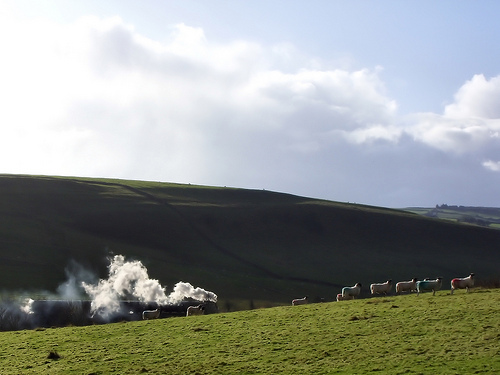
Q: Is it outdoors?
A: Yes, it is outdoors.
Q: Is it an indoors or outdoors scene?
A: It is outdoors.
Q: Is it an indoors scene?
A: No, it is outdoors.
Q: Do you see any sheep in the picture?
A: Yes, there is a sheep.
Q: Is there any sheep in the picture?
A: Yes, there is a sheep.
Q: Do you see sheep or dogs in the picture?
A: Yes, there is a sheep.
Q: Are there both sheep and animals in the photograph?
A: Yes, there are both a sheep and animals.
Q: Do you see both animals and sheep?
A: Yes, there are both a sheep and animals.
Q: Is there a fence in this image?
A: No, there are no fences.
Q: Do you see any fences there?
A: No, there are no fences.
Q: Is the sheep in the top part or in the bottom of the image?
A: The sheep is in the bottom of the image.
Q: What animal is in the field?
A: The animal is a sheep.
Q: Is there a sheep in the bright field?
A: Yes, there is a sheep in the field.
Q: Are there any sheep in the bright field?
A: Yes, there is a sheep in the field.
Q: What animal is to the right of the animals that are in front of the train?
A: The animal is a sheep.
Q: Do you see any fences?
A: No, there are no fences.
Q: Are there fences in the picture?
A: No, there are no fences.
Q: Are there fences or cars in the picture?
A: No, there are no fences or cars.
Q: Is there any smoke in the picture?
A: Yes, there is smoke.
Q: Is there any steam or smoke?
A: Yes, there is smoke.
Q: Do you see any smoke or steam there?
A: Yes, there is smoke.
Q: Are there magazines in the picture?
A: No, there are no magazines.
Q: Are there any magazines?
A: No, there are no magazines.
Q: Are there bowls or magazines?
A: No, there are no magazines or bowls.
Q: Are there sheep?
A: Yes, there is a sheep.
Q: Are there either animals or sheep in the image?
A: Yes, there is a sheep.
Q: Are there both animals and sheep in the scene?
A: Yes, there are both a sheep and animals.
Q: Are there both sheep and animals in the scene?
A: Yes, there are both a sheep and animals.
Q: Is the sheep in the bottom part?
A: Yes, the sheep is in the bottom of the image.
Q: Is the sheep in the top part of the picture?
A: No, the sheep is in the bottom of the image.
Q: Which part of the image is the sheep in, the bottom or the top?
A: The sheep is in the bottom of the image.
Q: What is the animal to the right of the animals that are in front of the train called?
A: The animal is a sheep.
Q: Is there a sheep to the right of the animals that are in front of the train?
A: Yes, there is a sheep to the right of the animals.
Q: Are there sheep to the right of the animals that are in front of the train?
A: Yes, there is a sheep to the right of the animals.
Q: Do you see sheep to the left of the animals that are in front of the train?
A: No, the sheep is to the right of the animals.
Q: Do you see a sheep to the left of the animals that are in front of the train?
A: No, the sheep is to the right of the animals.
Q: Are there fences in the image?
A: No, there are no fences.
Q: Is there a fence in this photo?
A: No, there are no fences.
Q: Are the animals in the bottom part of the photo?
A: Yes, the animals are in the bottom of the image.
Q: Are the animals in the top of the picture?
A: No, the animals are in the bottom of the image.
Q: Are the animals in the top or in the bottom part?
A: The animals are in the bottom of the image.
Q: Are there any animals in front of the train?
A: Yes, there are animals in front of the train.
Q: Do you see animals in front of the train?
A: Yes, there are animals in front of the train.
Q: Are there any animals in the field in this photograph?
A: Yes, there are animals in the field.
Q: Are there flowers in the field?
A: No, there are animals in the field.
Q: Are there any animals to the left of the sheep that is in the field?
A: Yes, there are animals to the left of the sheep.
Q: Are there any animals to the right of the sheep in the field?
A: No, the animals are to the left of the sheep.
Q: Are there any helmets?
A: No, there are no helmets.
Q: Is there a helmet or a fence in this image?
A: No, there are no helmets or fences.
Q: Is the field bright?
A: Yes, the field is bright.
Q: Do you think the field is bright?
A: Yes, the field is bright.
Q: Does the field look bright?
A: Yes, the field is bright.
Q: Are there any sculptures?
A: No, there are no sculptures.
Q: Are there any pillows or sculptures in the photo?
A: No, there are no sculptures or pillows.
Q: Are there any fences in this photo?
A: No, there are no fences.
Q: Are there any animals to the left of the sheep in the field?
A: Yes, there is an animal to the left of the sheep.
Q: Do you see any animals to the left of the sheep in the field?
A: Yes, there is an animal to the left of the sheep.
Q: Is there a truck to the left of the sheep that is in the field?
A: No, there is an animal to the left of the sheep.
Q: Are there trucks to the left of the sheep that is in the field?
A: No, there is an animal to the left of the sheep.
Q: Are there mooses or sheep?
A: Yes, there is a sheep.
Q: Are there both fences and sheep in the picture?
A: No, there is a sheep but no fences.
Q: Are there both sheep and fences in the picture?
A: No, there is a sheep but no fences.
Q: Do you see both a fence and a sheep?
A: No, there is a sheep but no fences.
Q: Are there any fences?
A: No, there are no fences.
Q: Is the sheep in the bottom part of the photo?
A: Yes, the sheep is in the bottom of the image.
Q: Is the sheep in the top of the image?
A: No, the sheep is in the bottom of the image.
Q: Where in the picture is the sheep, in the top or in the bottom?
A: The sheep is in the bottom of the image.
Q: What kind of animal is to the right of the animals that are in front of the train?
A: The animal is a sheep.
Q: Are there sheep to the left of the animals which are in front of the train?
A: No, the sheep is to the right of the animals.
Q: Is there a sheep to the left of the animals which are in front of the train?
A: No, the sheep is to the right of the animals.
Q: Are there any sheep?
A: Yes, there is a sheep.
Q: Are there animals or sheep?
A: Yes, there is a sheep.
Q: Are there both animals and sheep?
A: Yes, there are both a sheep and an animal.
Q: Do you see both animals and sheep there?
A: Yes, there are both a sheep and an animal.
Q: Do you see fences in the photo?
A: No, there are no fences.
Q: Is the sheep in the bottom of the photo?
A: Yes, the sheep is in the bottom of the image.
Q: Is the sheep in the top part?
A: No, the sheep is in the bottom of the image.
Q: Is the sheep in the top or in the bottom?
A: The sheep is in the bottom of the image.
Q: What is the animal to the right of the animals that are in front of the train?
A: The animal is a sheep.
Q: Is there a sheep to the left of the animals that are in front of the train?
A: No, the sheep is to the right of the animals.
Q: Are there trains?
A: Yes, there is a train.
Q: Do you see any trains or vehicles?
A: Yes, there is a train.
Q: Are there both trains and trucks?
A: No, there is a train but no trucks.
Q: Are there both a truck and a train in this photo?
A: No, there is a train but no trucks.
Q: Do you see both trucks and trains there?
A: No, there is a train but no trucks.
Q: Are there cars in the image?
A: No, there are no cars.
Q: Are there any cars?
A: No, there are no cars.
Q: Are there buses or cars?
A: No, there are no cars or buses.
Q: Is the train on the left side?
A: Yes, the train is on the left of the image.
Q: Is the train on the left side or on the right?
A: The train is on the left of the image.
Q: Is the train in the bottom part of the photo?
A: Yes, the train is in the bottom of the image.